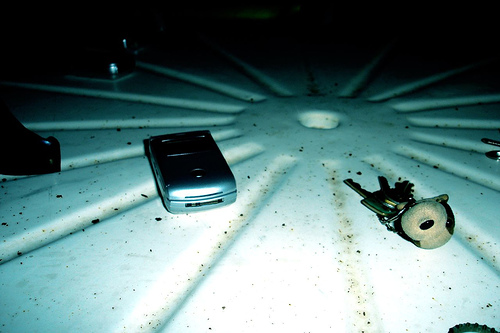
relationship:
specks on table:
[320, 144, 377, 180] [3, 4, 497, 329]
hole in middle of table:
[299, 110, 341, 131] [3, 4, 497, 329]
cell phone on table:
[147, 129, 237, 214] [3, 4, 497, 329]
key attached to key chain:
[341, 176, 448, 231] [376, 181, 472, 251]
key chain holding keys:
[400, 202, 455, 250] [342, 173, 414, 215]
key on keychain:
[341, 176, 448, 231] [383, 193, 463, 251]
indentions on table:
[39, 67, 467, 306] [0, 0, 500, 333]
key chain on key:
[400, 202, 455, 250] [386, 176, 417, 206]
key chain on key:
[400, 202, 455, 250] [371, 166, 397, 205]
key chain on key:
[400, 202, 455, 250] [341, 175, 393, 218]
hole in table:
[293, 106, 348, 131] [3, 4, 497, 329]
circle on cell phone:
[194, 173, 204, 180] [147, 129, 237, 214]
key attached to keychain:
[341, 176, 448, 231] [345, 157, 456, 249]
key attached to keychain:
[376, 167, 401, 197] [345, 157, 456, 249]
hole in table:
[299, 110, 341, 131] [3, 4, 497, 329]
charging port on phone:
[185, 196, 225, 205] [125, 81, 243, 244]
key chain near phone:
[400, 202, 455, 250] [142, 125, 238, 214]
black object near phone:
[1, 94, 70, 182] [142, 125, 238, 214]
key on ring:
[341, 176, 448, 231] [380, 180, 457, 250]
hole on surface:
[299, 110, 341, 131] [1, 11, 497, 329]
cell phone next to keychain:
[147, 129, 237, 214] [388, 187, 460, 243]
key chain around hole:
[400, 202, 455, 250] [295, 101, 343, 133]